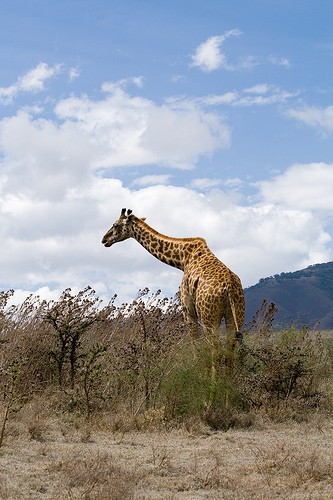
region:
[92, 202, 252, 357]
spotted giraffe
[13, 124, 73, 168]
white clouds in blue sky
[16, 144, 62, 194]
white clouds in blue sky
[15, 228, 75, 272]
white clouds in blue sky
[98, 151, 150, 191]
white clouds in blue sky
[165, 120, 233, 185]
white clouds in blue sky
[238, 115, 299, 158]
white clouds in blue sky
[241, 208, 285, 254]
white clouds in blue sky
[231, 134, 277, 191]
white clouds in blue sky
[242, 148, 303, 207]
white clouds in blue sky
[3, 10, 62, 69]
white clouds in blue ski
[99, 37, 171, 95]
white clouds in blue ski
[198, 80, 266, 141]
white clouds in blue ski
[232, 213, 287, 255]
white clouds in blue ski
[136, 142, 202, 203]
white clouds in blue ski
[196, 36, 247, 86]
white clouds in blue ski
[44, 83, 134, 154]
white clouds in blue ski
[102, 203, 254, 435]
a giraffe in the brush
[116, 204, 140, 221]
the horns on the giraffes head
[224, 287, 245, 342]
the tail of the giraffe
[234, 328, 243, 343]
the black furry end of the tail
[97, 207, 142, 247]
the head of the giraffe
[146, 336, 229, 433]
the green brush behind the giraffe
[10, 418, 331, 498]
the dry twigs and grass on the ground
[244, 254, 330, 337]
a hill in the distance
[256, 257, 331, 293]
the trees on the top of the hill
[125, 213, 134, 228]
the ear of the giraffe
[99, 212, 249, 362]
brown spotted giraffe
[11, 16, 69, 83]
white clouds in blue sky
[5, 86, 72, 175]
white clouds in blue sky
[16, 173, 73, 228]
white clouds in blue sky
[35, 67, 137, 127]
white clouds in blue sky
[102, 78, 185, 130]
white clouds in blue sky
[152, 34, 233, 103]
white clouds in blue sky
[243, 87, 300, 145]
white clouds in blue sky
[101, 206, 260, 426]
Tall giraffe in a field.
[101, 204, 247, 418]
Horned giraffe in field.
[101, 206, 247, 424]
Spotted giraffe in field.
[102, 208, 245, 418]
Adult giraffe in field.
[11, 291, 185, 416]
Row of weeds in field.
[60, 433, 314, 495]
Dry grassland in field.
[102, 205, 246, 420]
Tall giraffe in field.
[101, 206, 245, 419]
Giraffe traveling through field.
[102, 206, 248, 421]
Giraffe deep in weeds.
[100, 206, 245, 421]
Sleepy giraffe walking in field.